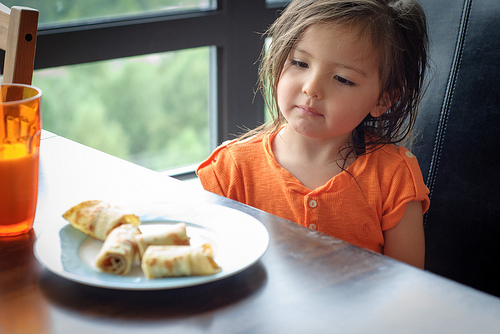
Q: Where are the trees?
A: In the window.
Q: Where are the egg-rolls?
A: On the plate.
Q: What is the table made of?
A: Wood.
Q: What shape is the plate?
A: Circle.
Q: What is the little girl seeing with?
A: Eyes.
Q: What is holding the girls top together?
A: Button.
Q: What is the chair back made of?
A: Leather.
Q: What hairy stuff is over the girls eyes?
A: Eyebrows.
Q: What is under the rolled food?
A: Plate.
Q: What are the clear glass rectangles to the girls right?
A: Windows.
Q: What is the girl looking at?
A: Food.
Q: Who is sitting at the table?
A: Girl.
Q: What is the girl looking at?
A: Plate of food.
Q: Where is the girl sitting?
A: In a booth.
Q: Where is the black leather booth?
A: Behind the girl.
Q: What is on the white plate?
A: Four sandwich rolls.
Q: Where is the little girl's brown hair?
A: On her head.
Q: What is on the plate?
A: Spring rolls.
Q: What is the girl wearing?
A: An orange shirt?.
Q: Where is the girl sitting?
A: In a booth.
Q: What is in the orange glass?
A: Milk.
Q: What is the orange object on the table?
A: A glass.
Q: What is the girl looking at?
A: Her plate.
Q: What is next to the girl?
A: A window.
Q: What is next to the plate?
A: An orange glass.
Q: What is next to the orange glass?
A: A plate of food.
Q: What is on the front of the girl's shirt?
A: Buttons.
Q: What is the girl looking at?
A: Food.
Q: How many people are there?
A: One.